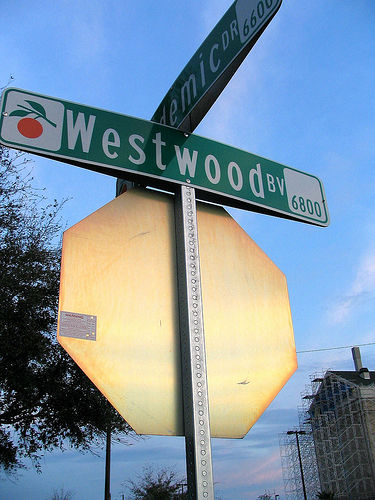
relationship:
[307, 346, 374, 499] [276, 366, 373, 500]
building has scaffolding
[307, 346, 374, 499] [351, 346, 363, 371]
building has chimney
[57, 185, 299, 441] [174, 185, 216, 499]
sign attached to pole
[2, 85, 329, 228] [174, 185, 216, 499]
sign attached to pole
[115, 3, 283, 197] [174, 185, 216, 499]
sign attached to pole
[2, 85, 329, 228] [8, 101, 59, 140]
sign has orange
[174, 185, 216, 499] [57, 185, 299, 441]
pole holds sign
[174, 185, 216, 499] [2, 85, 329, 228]
pole holds sign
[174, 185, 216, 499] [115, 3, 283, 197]
pole holds sign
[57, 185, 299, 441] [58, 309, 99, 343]
sign has label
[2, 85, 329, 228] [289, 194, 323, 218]
sign displays 6800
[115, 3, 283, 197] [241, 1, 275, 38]
sign displays 6600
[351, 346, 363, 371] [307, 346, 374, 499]
chimney on top of building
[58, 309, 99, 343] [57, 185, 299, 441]
label attached to sign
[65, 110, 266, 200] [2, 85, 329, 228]
word printed on sign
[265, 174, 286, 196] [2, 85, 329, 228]
word printed on sign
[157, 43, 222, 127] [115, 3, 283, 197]
word printed on sign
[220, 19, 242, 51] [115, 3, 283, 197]
word printed on sign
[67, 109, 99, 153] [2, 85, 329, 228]
letter printed on sign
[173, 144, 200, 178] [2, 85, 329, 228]
letter printed on sign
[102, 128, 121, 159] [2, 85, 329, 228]
letter printed on sign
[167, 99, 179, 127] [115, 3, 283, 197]
letter printed on sign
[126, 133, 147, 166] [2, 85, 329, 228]
letter printed on sign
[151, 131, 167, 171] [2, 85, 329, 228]
letter printed on sign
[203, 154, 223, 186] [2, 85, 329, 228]
letter printed on sign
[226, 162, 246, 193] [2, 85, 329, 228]
letter printed on sign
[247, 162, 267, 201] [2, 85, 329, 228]
letter printed on sign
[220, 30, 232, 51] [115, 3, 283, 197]
letter printed on sign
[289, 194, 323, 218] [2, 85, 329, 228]
6800 printed on sign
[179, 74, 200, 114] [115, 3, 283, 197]
letter printed on sign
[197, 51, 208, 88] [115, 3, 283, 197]
letter printed on sign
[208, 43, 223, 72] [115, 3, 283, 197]
letter printed on sign